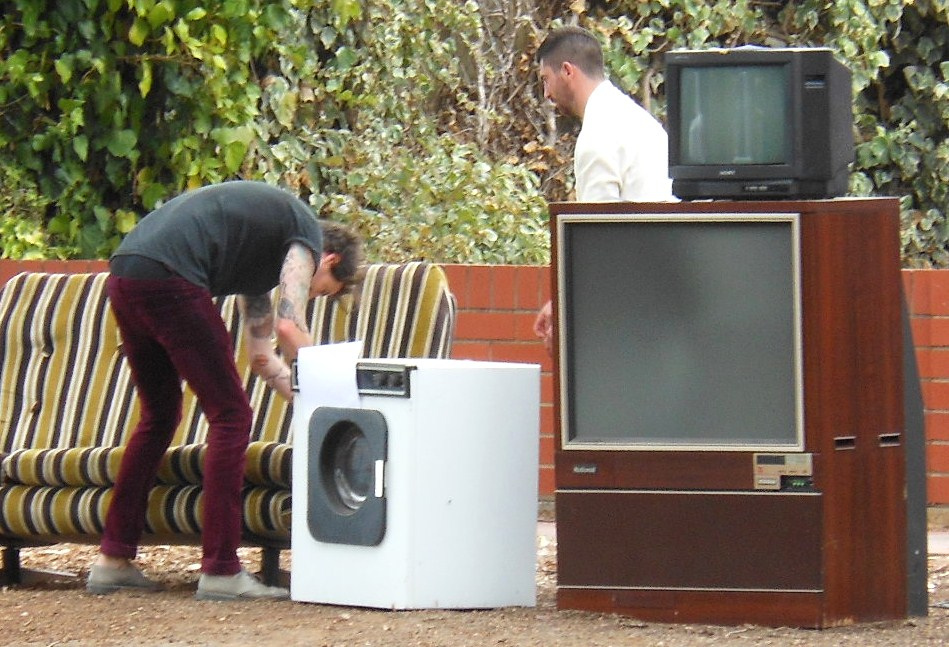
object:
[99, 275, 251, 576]
pants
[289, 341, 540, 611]
dryer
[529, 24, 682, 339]
man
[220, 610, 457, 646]
ground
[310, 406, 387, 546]
door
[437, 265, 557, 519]
wall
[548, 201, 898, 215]
top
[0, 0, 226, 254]
leaves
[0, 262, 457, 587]
couch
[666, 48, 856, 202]
television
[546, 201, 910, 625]
television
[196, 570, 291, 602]
shoe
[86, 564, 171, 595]
shoe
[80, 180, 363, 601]
man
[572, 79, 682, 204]
shirt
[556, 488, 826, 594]
speaker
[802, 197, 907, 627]
side